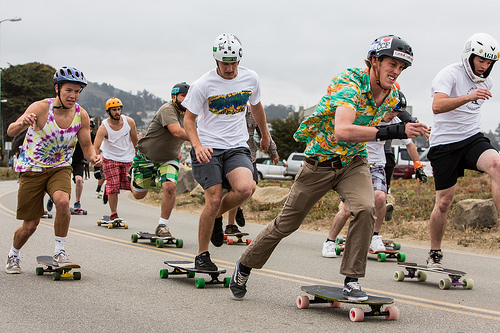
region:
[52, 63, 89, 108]
man in a blue helmet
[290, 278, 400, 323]
skateboard with pink wheels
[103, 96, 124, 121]
man in an orange helmet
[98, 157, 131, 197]
man in red plaid shorts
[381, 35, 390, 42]
heart symbol on a bumper sticker on a black helmet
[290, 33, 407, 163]
man in a Hawaiian print shirt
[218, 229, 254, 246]
skateboard with orange wheels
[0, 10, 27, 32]
white street light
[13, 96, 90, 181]
man in a tie-dye tank top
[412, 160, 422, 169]
man with an orange band on his wrist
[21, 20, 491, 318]
a group of guys skating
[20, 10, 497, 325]
skaters cruising on an open road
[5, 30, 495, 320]
a group of skaters racing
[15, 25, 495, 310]
a group of young men skateboarding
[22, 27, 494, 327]
racing on their skateboards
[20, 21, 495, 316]
racing their boards on the road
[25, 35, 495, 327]
trying to race their skateboards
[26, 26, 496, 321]
a group of young men skating on a street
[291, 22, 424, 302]
a skateboarder in a brightly colored button-up shirt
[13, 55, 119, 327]
a skateboarder in a tie-die tank top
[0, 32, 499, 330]
a group of people skateboarding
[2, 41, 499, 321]
people on skateboards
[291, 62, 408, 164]
green and yellow Hawaiian shirt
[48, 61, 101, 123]
blue helmet with a black strap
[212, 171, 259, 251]
leg is in the air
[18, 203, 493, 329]
two yellow stripes painted on the road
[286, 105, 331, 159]
shirt blowing in the wind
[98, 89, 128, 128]
yellow helmet with black straps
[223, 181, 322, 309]
leg extended back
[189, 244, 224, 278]
foot firmly planted on the skateboard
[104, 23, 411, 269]
Skateboarders going down the road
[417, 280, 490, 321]
Yellow paint on the road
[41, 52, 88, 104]
Man is wearing a blue helmet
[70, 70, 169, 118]
Mountain in the background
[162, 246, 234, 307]
Skateboard with green wheels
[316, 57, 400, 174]
Man wearing a Hawaiian shirt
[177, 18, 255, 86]
The man is wearing a white helmet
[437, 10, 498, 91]
Man wearing a motorcycle helmet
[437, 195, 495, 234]
Large rock on side of road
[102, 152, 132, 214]
Man wearing plaid shorts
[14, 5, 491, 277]
a group of people skateboarding on the road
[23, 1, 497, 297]
skateboarders on the road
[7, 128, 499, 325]
a yellow double line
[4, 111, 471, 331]
a yellow double line on the road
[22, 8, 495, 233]
a group of people wearing helmets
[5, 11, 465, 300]
skateboarders wearing helmets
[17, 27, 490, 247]
skateboarders on a road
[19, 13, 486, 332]
skateboarders skateboarding down a road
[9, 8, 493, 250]
men skateboarding on road